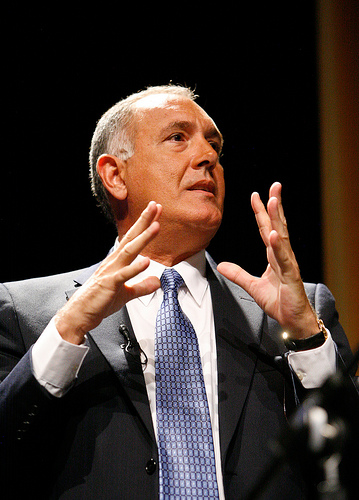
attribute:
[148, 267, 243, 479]
tie — blue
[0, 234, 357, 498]
suit — gray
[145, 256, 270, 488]
tie — blue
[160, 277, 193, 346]
tie — blue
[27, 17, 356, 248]
screen — black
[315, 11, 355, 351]
wall — brown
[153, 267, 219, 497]
tie — blue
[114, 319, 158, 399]
mic — black